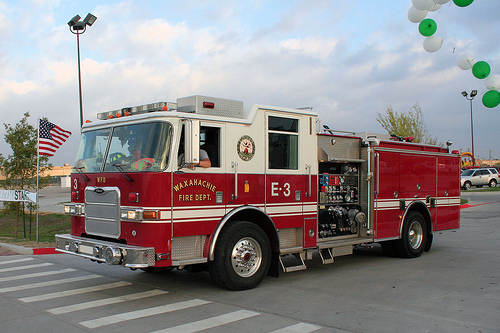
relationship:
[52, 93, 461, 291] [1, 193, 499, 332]
firetruck parked on street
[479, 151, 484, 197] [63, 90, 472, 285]
suv behind fire truck